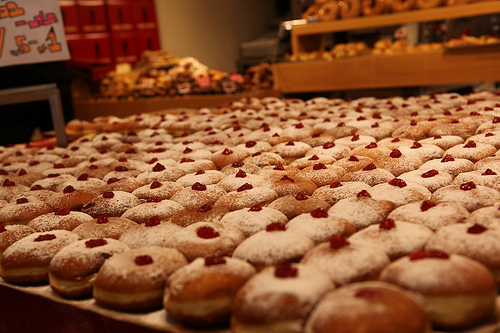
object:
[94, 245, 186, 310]
cream puff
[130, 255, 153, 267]
fruit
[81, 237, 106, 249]
fruit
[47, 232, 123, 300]
cream puff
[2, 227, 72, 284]
cream puff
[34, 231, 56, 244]
fruit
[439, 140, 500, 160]
cream puffs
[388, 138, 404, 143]
fruit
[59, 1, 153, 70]
box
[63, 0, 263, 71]
wall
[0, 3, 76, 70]
sign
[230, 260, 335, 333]
doughnut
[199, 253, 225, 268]
jelly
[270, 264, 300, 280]
jelly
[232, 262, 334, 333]
pastry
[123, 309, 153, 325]
table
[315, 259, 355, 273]
sugar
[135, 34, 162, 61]
container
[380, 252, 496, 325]
pastries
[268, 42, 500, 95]
stand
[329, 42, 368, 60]
pastries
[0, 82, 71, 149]
table